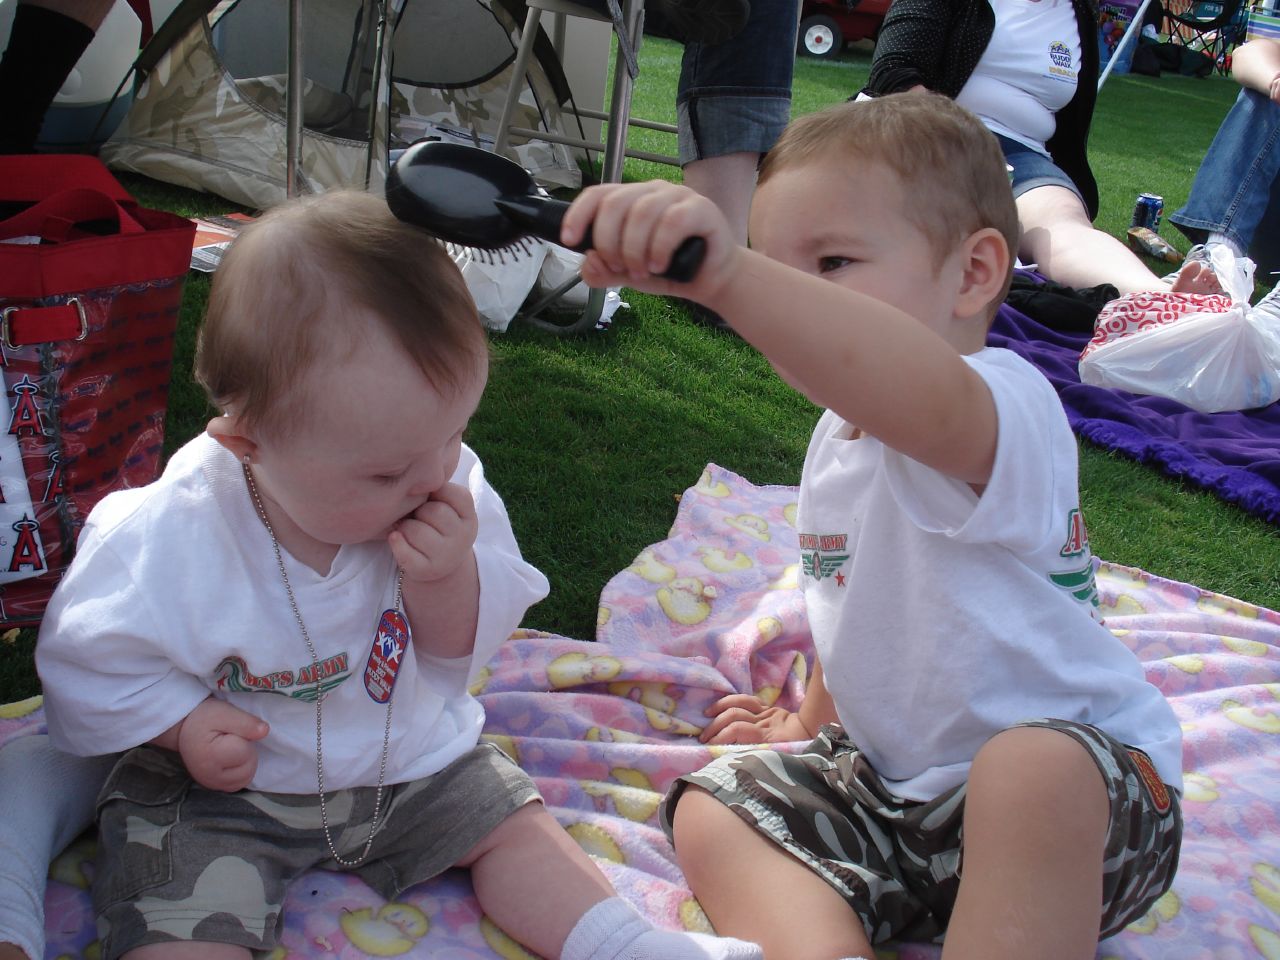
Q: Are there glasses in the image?
A: No, there are no glasses.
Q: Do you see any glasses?
A: No, there are no glasses.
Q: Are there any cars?
A: No, there are no cars.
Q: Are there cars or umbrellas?
A: No, there are no cars or umbrellas.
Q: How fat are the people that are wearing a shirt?
A: The people are fat.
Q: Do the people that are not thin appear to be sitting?
A: Yes, the people are sitting.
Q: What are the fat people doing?
A: The people are sitting.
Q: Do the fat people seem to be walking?
A: No, the people are sitting.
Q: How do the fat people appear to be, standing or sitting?
A: The people are sitting.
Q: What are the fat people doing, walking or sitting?
A: The people are sitting.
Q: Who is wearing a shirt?
A: The people are wearing a shirt.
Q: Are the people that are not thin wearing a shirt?
A: Yes, the people are wearing a shirt.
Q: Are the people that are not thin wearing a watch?
A: No, the people are wearing a shirt.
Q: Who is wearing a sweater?
A: The people are wearing a sweater.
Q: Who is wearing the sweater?
A: The people are wearing a sweater.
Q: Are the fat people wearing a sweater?
A: Yes, the people are wearing a sweater.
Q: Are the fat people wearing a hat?
A: No, the people are wearing a sweater.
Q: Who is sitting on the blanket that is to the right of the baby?
A: The people are sitting on the blanket.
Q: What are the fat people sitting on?
A: The people are sitting on the blanket.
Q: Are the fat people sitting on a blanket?
A: Yes, the people are sitting on a blanket.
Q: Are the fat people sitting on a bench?
A: No, the people are sitting on a blanket.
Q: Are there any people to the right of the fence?
A: Yes, there are people to the right of the fence.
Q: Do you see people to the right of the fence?
A: Yes, there are people to the right of the fence.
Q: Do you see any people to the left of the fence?
A: No, the people are to the right of the fence.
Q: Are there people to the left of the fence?
A: No, the people are to the right of the fence.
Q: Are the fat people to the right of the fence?
A: Yes, the people are to the right of the fence.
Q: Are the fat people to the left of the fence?
A: No, the people are to the right of the fence.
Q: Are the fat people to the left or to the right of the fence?
A: The people are to the right of the fence.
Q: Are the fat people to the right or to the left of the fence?
A: The people are to the right of the fence.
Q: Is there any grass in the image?
A: Yes, there is grass.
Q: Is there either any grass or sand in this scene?
A: Yes, there is grass.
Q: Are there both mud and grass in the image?
A: No, there is grass but no mud.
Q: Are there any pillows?
A: No, there are no pillows.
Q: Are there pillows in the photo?
A: No, there are no pillows.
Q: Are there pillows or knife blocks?
A: No, there are no pillows or knife blocks.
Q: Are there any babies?
A: Yes, there is a baby.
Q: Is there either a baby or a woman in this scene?
A: Yes, there is a baby.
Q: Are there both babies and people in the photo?
A: Yes, there are both a baby and people.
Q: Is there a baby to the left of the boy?
A: Yes, there is a baby to the left of the boy.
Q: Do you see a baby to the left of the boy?
A: Yes, there is a baby to the left of the boy.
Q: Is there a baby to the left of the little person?
A: Yes, there is a baby to the left of the boy.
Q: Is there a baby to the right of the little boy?
A: No, the baby is to the left of the boy.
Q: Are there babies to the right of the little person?
A: No, the baby is to the left of the boy.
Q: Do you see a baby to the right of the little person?
A: No, the baby is to the left of the boy.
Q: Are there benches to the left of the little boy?
A: No, there is a baby to the left of the boy.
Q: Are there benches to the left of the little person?
A: No, there is a baby to the left of the boy.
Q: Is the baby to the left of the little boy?
A: Yes, the baby is to the left of the boy.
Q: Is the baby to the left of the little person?
A: Yes, the baby is to the left of the boy.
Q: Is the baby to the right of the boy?
A: No, the baby is to the left of the boy.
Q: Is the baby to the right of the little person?
A: No, the baby is to the left of the boy.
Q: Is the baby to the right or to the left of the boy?
A: The baby is to the left of the boy.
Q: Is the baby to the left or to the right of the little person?
A: The baby is to the left of the boy.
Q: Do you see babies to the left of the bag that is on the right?
A: Yes, there is a baby to the left of the bag.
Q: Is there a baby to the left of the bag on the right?
A: Yes, there is a baby to the left of the bag.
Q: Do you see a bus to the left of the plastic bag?
A: No, there is a baby to the left of the bag.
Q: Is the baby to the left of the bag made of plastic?
A: Yes, the baby is to the left of the bag.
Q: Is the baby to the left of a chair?
A: No, the baby is to the left of the bag.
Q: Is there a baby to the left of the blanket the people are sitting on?
A: Yes, there is a baby to the left of the blanket.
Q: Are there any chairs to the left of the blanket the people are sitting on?
A: No, there is a baby to the left of the blanket.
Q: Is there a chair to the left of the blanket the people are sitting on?
A: No, there is a baby to the left of the blanket.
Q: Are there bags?
A: Yes, there is a bag.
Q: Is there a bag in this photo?
A: Yes, there is a bag.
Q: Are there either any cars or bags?
A: Yes, there is a bag.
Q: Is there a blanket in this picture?
A: Yes, there is a blanket.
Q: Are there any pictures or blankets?
A: Yes, there is a blanket.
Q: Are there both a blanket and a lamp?
A: No, there is a blanket but no lamps.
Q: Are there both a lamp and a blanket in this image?
A: No, there is a blanket but no lamps.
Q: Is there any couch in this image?
A: No, there are no couches.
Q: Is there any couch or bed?
A: No, there are no couches or beds.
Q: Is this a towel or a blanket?
A: This is a blanket.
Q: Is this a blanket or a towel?
A: This is a blanket.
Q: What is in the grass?
A: The blanket is in the grass.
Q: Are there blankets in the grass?
A: Yes, there is a blanket in the grass.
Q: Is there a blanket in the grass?
A: Yes, there is a blanket in the grass.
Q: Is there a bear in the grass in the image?
A: No, there is a blanket in the grass.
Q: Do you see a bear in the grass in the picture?
A: No, there is a blanket in the grass.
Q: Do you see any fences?
A: Yes, there is a fence.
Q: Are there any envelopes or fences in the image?
A: Yes, there is a fence.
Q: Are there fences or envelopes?
A: Yes, there is a fence.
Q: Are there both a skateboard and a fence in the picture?
A: No, there is a fence but no skateboards.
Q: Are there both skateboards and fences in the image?
A: No, there is a fence but no skateboards.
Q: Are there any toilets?
A: No, there are no toilets.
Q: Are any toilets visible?
A: No, there are no toilets.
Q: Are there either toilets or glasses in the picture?
A: No, there are no toilets or glasses.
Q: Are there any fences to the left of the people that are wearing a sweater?
A: Yes, there is a fence to the left of the people.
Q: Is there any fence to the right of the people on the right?
A: No, the fence is to the left of the people.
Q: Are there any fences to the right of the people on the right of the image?
A: No, the fence is to the left of the people.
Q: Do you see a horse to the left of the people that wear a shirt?
A: No, there is a fence to the left of the people.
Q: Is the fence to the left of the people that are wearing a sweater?
A: Yes, the fence is to the left of the people.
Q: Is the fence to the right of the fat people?
A: No, the fence is to the left of the people.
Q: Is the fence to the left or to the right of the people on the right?
A: The fence is to the left of the people.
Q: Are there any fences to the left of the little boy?
A: Yes, there is a fence to the left of the boy.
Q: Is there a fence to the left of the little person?
A: Yes, there is a fence to the left of the boy.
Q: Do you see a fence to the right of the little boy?
A: No, the fence is to the left of the boy.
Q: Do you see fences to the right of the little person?
A: No, the fence is to the left of the boy.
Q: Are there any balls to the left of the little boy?
A: No, there is a fence to the left of the boy.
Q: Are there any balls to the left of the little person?
A: No, there is a fence to the left of the boy.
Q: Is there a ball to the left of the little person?
A: No, there is a fence to the left of the boy.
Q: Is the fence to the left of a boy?
A: Yes, the fence is to the left of a boy.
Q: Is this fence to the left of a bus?
A: No, the fence is to the left of a boy.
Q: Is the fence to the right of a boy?
A: No, the fence is to the left of a boy.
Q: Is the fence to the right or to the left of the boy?
A: The fence is to the left of the boy.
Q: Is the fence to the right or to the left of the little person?
A: The fence is to the left of the boy.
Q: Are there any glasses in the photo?
A: No, there are no glasses.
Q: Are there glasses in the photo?
A: No, there are no glasses.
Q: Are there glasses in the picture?
A: No, there are no glasses.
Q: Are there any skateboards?
A: No, there are no skateboards.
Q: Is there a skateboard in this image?
A: No, there are no skateboards.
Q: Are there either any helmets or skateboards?
A: No, there are no skateboards or helmets.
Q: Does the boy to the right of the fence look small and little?
A: Yes, the boy is small and little.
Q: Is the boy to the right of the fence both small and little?
A: Yes, the boy is small and little.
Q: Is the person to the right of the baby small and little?
A: Yes, the boy is small and little.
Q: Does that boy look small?
A: Yes, the boy is small.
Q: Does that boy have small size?
A: Yes, the boy is small.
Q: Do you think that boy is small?
A: Yes, the boy is small.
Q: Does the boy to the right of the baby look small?
A: Yes, the boy is small.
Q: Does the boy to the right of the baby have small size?
A: Yes, the boy is small.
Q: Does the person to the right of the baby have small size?
A: Yes, the boy is small.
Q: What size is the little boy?
A: The boy is small.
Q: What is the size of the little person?
A: The boy is small.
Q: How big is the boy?
A: The boy is small.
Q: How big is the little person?
A: The boy is small.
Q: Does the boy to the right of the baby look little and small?
A: Yes, the boy is little and small.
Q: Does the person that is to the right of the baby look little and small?
A: Yes, the boy is little and small.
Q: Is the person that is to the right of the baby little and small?
A: Yes, the boy is little and small.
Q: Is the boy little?
A: Yes, the boy is little.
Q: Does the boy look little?
A: Yes, the boy is little.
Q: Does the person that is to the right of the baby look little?
A: Yes, the boy is little.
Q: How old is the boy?
A: The boy is little.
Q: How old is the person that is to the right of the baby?
A: The boy is little.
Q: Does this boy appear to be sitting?
A: Yes, the boy is sitting.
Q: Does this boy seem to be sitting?
A: Yes, the boy is sitting.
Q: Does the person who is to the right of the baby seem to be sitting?
A: Yes, the boy is sitting.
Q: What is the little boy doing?
A: The boy is sitting.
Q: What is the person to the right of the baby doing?
A: The boy is sitting.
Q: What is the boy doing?
A: The boy is sitting.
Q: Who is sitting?
A: The boy is sitting.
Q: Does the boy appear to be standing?
A: No, the boy is sitting.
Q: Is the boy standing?
A: No, the boy is sitting.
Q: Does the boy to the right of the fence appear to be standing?
A: No, the boy is sitting.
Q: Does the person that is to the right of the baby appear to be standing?
A: No, the boy is sitting.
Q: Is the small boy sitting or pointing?
A: The boy is sitting.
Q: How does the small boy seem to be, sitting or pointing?
A: The boy is sitting.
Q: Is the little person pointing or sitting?
A: The boy is sitting.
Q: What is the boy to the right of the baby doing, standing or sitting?
A: The boy is sitting.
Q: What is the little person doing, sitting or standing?
A: The boy is sitting.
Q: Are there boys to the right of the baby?
A: Yes, there is a boy to the right of the baby.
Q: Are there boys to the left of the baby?
A: No, the boy is to the right of the baby.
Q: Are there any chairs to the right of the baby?
A: No, there is a boy to the right of the baby.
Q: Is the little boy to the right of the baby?
A: Yes, the boy is to the right of the baby.